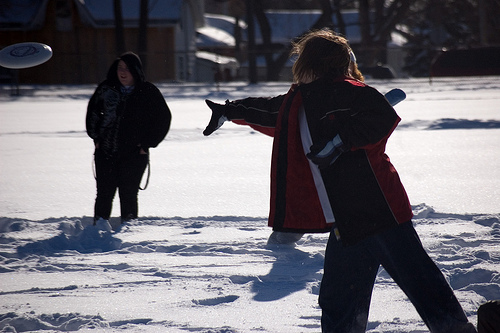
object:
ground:
[163, 280, 265, 312]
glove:
[306, 124, 368, 170]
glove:
[203, 99, 237, 136]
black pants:
[92, 145, 151, 226]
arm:
[203, 94, 287, 136]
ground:
[0, 73, 65, 195]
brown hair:
[288, 27, 365, 86]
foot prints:
[191, 294, 240, 307]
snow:
[185, 314, 285, 327]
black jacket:
[86, 78, 172, 153]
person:
[84, 52, 171, 225]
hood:
[106, 51, 146, 84]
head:
[117, 52, 142, 86]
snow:
[428, 130, 496, 164]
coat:
[225, 77, 414, 233]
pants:
[317, 202, 476, 333]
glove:
[186, 88, 227, 148]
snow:
[170, 251, 202, 295]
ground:
[173, 138, 239, 215]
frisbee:
[0, 42, 53, 68]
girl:
[203, 26, 475, 333]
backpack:
[476, 300, 499, 333]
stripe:
[297, 106, 340, 240]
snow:
[14, 149, 51, 225]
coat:
[84, 78, 172, 154]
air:
[3, 70, 53, 96]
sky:
[0, 0, 500, 54]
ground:
[424, 86, 485, 180]